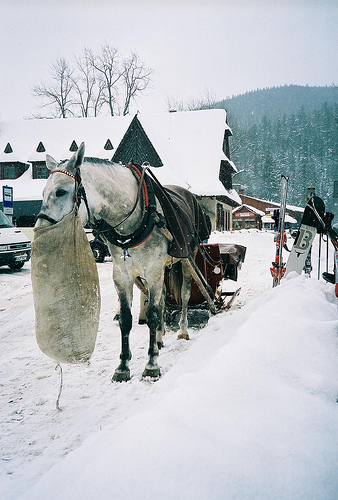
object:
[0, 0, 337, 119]
clouds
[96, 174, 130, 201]
fur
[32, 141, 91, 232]
head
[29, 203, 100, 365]
feed bag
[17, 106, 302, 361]
horse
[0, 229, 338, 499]
snow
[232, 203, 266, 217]
roof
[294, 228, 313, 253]
letter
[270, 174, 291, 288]
skis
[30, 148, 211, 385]
horse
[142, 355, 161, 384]
hoof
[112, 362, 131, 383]
hoof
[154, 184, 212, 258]
blanket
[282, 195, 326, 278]
skis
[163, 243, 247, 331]
sleigh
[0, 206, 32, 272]
car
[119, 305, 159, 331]
knees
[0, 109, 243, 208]
snow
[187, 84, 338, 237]
mountains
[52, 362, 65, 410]
string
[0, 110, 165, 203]
roof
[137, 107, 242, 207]
roof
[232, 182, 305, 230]
building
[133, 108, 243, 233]
building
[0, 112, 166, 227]
building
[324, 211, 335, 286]
rack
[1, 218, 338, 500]
street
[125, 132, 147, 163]
designs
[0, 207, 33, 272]
van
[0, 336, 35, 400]
nearby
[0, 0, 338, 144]
sky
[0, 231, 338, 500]
ground